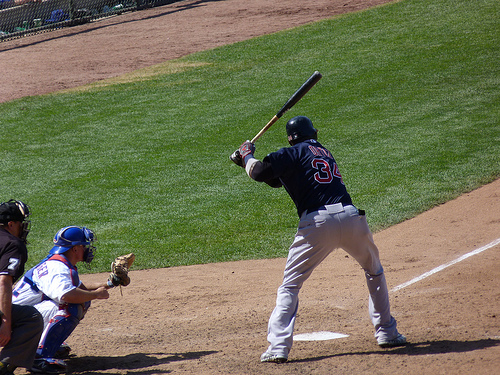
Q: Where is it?
A: This is at the field.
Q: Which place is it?
A: It is a field.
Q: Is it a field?
A: Yes, it is a field.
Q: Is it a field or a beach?
A: It is a field.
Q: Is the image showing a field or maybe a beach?
A: It is showing a field.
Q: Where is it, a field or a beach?
A: It is a field.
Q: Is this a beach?
A: No, it is a field.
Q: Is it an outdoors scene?
A: Yes, it is outdoors.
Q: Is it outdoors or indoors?
A: It is outdoors.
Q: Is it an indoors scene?
A: No, it is outdoors.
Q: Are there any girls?
A: No, there are no girls.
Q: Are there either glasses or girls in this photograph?
A: No, there are no girls or glasses.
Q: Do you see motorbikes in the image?
A: No, there are no motorbikes.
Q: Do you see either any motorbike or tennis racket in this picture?
A: No, there are no motorcycles or rackets.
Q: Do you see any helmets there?
A: Yes, there is a helmet.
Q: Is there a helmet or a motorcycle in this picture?
A: Yes, there is a helmet.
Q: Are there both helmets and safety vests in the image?
A: No, there is a helmet but no safety jackets.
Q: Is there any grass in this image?
A: Yes, there is grass.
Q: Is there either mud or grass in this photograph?
A: Yes, there is grass.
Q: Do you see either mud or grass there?
A: Yes, there is grass.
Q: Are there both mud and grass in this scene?
A: No, there is grass but no mud.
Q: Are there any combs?
A: No, there are no combs.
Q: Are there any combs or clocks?
A: No, there are no combs or clocks.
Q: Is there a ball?
A: No, there are no balls.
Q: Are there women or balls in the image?
A: No, there are no balls or women.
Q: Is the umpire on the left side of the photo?
A: Yes, the umpire is on the left of the image.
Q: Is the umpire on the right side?
A: No, the umpire is on the left of the image.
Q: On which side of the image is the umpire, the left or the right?
A: The umpire is on the left of the image.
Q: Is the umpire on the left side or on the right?
A: The umpire is on the left of the image.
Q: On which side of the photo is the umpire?
A: The umpire is on the left of the image.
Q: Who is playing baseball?
A: The umpire is playing baseball.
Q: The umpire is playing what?
A: The umpire is playing baseball.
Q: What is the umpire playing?
A: The umpire is playing baseball.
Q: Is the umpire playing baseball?
A: Yes, the umpire is playing baseball.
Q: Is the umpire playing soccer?
A: No, the umpire is playing baseball.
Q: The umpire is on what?
A: The umpire is on the mound.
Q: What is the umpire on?
A: The umpire is on the mound.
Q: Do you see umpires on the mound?
A: Yes, there is an umpire on the mound.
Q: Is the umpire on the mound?
A: Yes, the umpire is on the mound.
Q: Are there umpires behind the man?
A: Yes, there is an umpire behind the man.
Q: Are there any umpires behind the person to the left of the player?
A: Yes, there is an umpire behind the man.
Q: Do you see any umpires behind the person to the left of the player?
A: Yes, there is an umpire behind the man.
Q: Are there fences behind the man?
A: No, there is an umpire behind the man.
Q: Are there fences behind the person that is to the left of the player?
A: No, there is an umpire behind the man.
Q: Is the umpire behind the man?
A: Yes, the umpire is behind the man.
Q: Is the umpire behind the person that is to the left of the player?
A: Yes, the umpire is behind the man.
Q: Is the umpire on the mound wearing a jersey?
A: Yes, the umpire is wearing a jersey.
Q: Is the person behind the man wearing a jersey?
A: Yes, the umpire is wearing a jersey.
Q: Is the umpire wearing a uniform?
A: No, the umpire is wearing a jersey.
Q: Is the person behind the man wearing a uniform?
A: No, the umpire is wearing a jersey.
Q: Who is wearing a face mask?
A: The umpire is wearing a face mask.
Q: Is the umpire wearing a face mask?
A: Yes, the umpire is wearing a face mask.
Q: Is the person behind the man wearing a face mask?
A: Yes, the umpire is wearing a face mask.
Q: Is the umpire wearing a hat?
A: No, the umpire is wearing a face mask.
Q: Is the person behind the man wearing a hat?
A: No, the umpire is wearing a face mask.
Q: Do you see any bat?
A: Yes, there is a bat.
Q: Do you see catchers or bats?
A: Yes, there is a bat.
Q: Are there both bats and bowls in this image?
A: No, there is a bat but no bowls.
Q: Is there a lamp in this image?
A: No, there are no lamps.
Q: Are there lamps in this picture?
A: No, there are no lamps.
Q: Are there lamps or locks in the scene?
A: No, there are no lamps or locks.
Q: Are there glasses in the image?
A: No, there are no glasses.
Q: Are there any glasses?
A: No, there are no glasses.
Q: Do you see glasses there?
A: No, there are no glasses.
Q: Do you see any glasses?
A: No, there are no glasses.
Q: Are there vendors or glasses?
A: No, there are no glasses or vendors.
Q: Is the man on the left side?
A: Yes, the man is on the left of the image.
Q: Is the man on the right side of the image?
A: No, the man is on the left of the image.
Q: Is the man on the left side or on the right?
A: The man is on the left of the image.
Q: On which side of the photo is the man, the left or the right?
A: The man is on the left of the image.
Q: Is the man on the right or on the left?
A: The man is on the left of the image.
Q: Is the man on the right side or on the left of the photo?
A: The man is on the left of the image.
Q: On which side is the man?
A: The man is on the left of the image.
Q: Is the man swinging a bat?
A: Yes, the man is swinging a bat.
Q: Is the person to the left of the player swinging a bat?
A: Yes, the man is swinging a bat.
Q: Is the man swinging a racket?
A: No, the man is swinging a bat.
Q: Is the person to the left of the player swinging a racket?
A: No, the man is swinging a bat.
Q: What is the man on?
A: The man is on the mound.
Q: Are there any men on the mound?
A: Yes, there is a man on the mound.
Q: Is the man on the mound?
A: Yes, the man is on the mound.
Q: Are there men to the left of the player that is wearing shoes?
A: Yes, there is a man to the left of the player.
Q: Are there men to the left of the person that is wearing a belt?
A: Yes, there is a man to the left of the player.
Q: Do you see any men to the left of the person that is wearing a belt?
A: Yes, there is a man to the left of the player.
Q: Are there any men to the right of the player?
A: No, the man is to the left of the player.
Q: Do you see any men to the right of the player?
A: No, the man is to the left of the player.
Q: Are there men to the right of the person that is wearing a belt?
A: No, the man is to the left of the player.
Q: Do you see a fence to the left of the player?
A: No, there is a man to the left of the player.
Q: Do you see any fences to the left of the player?
A: No, there is a man to the left of the player.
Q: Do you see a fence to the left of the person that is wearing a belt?
A: No, there is a man to the left of the player.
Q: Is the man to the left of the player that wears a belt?
A: Yes, the man is to the left of the player.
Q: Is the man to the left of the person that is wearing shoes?
A: Yes, the man is to the left of the player.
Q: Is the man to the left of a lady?
A: No, the man is to the left of the player.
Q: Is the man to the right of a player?
A: No, the man is to the left of a player.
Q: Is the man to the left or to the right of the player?
A: The man is to the left of the player.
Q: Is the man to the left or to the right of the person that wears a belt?
A: The man is to the left of the player.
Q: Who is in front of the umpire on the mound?
A: The man is in front of the umpire.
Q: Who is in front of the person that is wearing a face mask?
A: The man is in front of the umpire.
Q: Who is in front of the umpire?
A: The man is in front of the umpire.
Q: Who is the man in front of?
A: The man is in front of the umpire.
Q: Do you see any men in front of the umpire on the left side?
A: Yes, there is a man in front of the umpire.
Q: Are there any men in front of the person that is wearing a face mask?
A: Yes, there is a man in front of the umpire.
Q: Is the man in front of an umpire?
A: Yes, the man is in front of an umpire.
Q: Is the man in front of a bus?
A: No, the man is in front of an umpire.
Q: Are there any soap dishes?
A: No, there are no soap dishes.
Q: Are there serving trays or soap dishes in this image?
A: No, there are no soap dishes or serving trays.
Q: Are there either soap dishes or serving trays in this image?
A: No, there are no soap dishes or serving trays.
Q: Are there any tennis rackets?
A: No, there are no tennis rackets.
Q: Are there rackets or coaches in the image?
A: No, there are no rackets or coaches.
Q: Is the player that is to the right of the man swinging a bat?
A: Yes, the player is swinging a bat.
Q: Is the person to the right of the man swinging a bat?
A: Yes, the player is swinging a bat.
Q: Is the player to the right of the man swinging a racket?
A: No, the player is swinging a bat.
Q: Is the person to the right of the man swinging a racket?
A: No, the player is swinging a bat.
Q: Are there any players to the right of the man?
A: Yes, there is a player to the right of the man.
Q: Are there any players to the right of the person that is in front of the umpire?
A: Yes, there is a player to the right of the man.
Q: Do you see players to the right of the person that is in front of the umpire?
A: Yes, there is a player to the right of the man.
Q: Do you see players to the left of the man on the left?
A: No, the player is to the right of the man.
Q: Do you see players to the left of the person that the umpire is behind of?
A: No, the player is to the right of the man.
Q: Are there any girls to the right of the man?
A: No, there is a player to the right of the man.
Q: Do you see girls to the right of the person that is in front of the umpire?
A: No, there is a player to the right of the man.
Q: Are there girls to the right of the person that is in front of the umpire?
A: No, there is a player to the right of the man.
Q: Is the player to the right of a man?
A: Yes, the player is to the right of a man.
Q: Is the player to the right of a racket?
A: No, the player is to the right of a man.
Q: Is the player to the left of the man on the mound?
A: No, the player is to the right of the man.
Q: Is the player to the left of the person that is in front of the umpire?
A: No, the player is to the right of the man.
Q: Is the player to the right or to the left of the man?
A: The player is to the right of the man.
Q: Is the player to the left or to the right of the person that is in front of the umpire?
A: The player is to the right of the man.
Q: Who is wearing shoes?
A: The player is wearing shoes.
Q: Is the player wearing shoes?
A: Yes, the player is wearing shoes.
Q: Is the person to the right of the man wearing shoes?
A: Yes, the player is wearing shoes.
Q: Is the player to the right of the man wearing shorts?
A: No, the player is wearing shoes.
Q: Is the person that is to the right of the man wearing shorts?
A: No, the player is wearing shoes.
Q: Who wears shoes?
A: The player wears shoes.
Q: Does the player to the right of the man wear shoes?
A: Yes, the player wears shoes.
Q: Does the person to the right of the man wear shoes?
A: Yes, the player wears shoes.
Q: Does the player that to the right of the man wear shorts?
A: No, the player wears shoes.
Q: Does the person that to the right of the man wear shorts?
A: No, the player wears shoes.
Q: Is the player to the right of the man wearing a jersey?
A: Yes, the player is wearing a jersey.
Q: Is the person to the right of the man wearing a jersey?
A: Yes, the player is wearing a jersey.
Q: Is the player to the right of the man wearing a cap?
A: No, the player is wearing a jersey.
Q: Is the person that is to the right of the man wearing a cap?
A: No, the player is wearing a jersey.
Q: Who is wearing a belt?
A: The player is wearing a belt.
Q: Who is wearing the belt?
A: The player is wearing a belt.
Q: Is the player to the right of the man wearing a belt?
A: Yes, the player is wearing a belt.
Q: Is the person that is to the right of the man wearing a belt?
A: Yes, the player is wearing a belt.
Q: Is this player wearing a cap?
A: No, the player is wearing a belt.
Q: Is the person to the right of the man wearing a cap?
A: No, the player is wearing a belt.